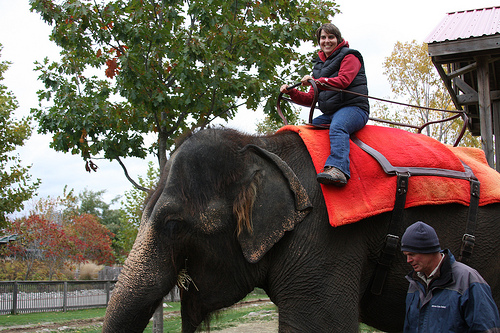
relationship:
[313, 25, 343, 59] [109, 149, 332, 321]
woman riding an elephant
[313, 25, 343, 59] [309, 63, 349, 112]
woman with vest